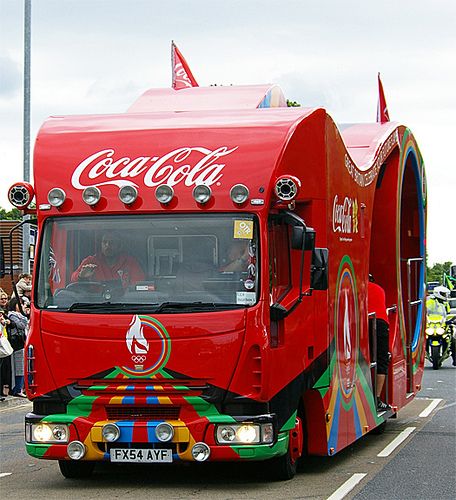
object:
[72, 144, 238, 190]
lettering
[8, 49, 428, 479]
bus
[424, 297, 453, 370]
motorcycle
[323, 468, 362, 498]
line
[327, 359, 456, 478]
road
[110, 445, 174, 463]
license plate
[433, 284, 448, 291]
helmet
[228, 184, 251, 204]
lights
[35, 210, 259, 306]
windshield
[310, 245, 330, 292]
mirror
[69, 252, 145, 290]
jacket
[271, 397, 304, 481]
wheel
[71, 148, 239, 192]
coca cola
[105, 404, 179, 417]
grill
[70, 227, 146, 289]
driver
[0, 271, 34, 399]
crowd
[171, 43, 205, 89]
flag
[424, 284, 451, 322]
man